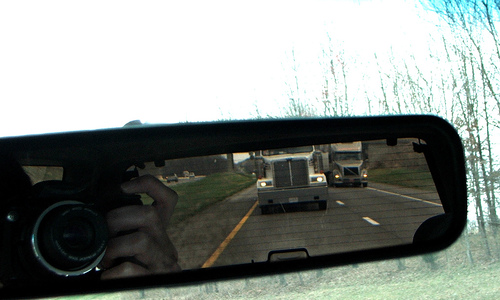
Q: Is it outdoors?
A: Yes, it is outdoors.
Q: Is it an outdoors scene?
A: Yes, it is outdoors.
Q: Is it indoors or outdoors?
A: It is outdoors.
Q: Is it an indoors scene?
A: No, it is outdoors.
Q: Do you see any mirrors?
A: Yes, there is a mirror.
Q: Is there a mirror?
A: Yes, there is a mirror.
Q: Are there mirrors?
A: Yes, there is a mirror.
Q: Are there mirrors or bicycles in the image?
A: Yes, there is a mirror.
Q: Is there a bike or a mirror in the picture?
A: Yes, there is a mirror.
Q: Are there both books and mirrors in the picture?
A: No, there is a mirror but no books.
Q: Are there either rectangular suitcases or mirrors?
A: Yes, there is a rectangular mirror.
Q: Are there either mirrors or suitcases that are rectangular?
A: Yes, the mirror is rectangular.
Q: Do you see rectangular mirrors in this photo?
A: Yes, there is a rectangular mirror.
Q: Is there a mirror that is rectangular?
A: Yes, there is a mirror that is rectangular.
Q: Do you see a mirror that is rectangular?
A: Yes, there is a mirror that is rectangular.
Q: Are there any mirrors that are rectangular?
A: Yes, there is a mirror that is rectangular.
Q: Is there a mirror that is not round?
A: Yes, there is a rectangular mirror.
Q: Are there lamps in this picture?
A: No, there are no lamps.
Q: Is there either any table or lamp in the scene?
A: No, there are no lamps or tables.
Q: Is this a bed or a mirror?
A: This is a mirror.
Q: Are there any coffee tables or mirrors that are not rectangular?
A: No, there is a mirror but it is rectangular.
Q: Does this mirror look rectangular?
A: Yes, the mirror is rectangular.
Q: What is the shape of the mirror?
A: The mirror is rectangular.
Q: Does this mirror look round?
A: No, the mirror is rectangular.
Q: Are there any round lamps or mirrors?
A: No, there is a mirror but it is rectangular.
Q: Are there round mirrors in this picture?
A: No, there is a mirror but it is rectangular.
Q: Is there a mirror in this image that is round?
A: No, there is a mirror but it is rectangular.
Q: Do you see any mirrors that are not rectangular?
A: No, there is a mirror but it is rectangular.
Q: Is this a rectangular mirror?
A: Yes, this is a rectangular mirror.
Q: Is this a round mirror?
A: No, this is a rectangular mirror.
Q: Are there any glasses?
A: No, there are no glasses.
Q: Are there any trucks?
A: Yes, there are trucks.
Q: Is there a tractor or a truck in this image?
A: Yes, there are trucks.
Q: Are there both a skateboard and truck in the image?
A: No, there are trucks but no skateboards.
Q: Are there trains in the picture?
A: No, there are no trains.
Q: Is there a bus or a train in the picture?
A: No, there are no trains or buses.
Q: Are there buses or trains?
A: No, there are no trains or buses.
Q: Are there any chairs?
A: No, there are no chairs.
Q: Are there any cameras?
A: Yes, there is a camera.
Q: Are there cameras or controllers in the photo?
A: Yes, there is a camera.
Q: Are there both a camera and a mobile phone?
A: No, there is a camera but no cell phones.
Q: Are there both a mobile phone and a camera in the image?
A: No, there is a camera but no cell phones.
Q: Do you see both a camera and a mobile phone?
A: No, there is a camera but no cell phones.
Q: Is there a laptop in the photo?
A: No, there are no laptops.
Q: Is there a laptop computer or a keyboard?
A: No, there are no laptops or keyboards.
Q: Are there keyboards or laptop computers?
A: No, there are no laptop computers or keyboards.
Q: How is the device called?
A: The device is a camera.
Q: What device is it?
A: The device is a camera.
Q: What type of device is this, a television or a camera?
A: This is a camera.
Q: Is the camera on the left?
A: Yes, the camera is on the left of the image.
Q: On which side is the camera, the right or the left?
A: The camera is on the left of the image.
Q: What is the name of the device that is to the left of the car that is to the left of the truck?
A: The device is a camera.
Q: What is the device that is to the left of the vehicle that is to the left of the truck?
A: The device is a camera.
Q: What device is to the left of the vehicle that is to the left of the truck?
A: The device is a camera.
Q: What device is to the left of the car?
A: The device is a camera.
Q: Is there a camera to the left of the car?
A: Yes, there is a camera to the left of the car.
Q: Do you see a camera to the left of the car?
A: Yes, there is a camera to the left of the car.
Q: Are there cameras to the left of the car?
A: Yes, there is a camera to the left of the car.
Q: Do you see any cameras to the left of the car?
A: Yes, there is a camera to the left of the car.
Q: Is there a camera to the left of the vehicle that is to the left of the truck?
A: Yes, there is a camera to the left of the car.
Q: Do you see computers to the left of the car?
A: No, there is a camera to the left of the car.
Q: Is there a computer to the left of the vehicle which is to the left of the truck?
A: No, there is a camera to the left of the car.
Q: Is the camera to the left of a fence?
A: No, the camera is to the left of a car.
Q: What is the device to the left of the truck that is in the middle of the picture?
A: The device is a camera.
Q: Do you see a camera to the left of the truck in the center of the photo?
A: Yes, there is a camera to the left of the truck.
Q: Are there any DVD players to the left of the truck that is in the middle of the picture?
A: No, there is a camera to the left of the truck.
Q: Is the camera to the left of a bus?
A: No, the camera is to the left of the truck.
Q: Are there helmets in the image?
A: No, there are no helmets.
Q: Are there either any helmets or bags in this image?
A: No, there are no helmets or bags.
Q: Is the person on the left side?
A: Yes, the person is on the left of the image.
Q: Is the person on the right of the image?
A: No, the person is on the left of the image.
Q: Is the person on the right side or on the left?
A: The person is on the left of the image.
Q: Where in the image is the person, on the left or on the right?
A: The person is on the left of the image.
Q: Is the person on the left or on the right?
A: The person is on the left of the image.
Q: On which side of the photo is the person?
A: The person is on the left of the image.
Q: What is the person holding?
A: The person is holding the camera.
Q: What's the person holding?
A: The person is holding the camera.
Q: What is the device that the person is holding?
A: The device is a camera.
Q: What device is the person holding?
A: The person is holding the camera.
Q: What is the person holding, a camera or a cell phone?
A: The person is holding a camera.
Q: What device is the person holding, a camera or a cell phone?
A: The person is holding a camera.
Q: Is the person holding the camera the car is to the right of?
A: Yes, the person is holding the camera.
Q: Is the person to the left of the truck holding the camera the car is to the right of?
A: Yes, the person is holding the camera.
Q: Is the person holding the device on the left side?
A: Yes, the person is holding the camera.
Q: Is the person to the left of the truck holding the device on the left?
A: Yes, the person is holding the camera.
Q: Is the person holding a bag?
A: No, the person is holding the camera.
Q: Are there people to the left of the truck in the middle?
A: Yes, there is a person to the left of the truck.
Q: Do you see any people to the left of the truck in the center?
A: Yes, there is a person to the left of the truck.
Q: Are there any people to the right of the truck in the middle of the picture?
A: No, the person is to the left of the truck.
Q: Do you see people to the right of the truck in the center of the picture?
A: No, the person is to the left of the truck.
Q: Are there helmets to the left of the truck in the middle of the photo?
A: No, there is a person to the left of the truck.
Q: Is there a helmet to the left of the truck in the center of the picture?
A: No, there is a person to the left of the truck.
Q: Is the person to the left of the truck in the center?
A: Yes, the person is to the left of the truck.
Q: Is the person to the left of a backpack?
A: No, the person is to the left of the truck.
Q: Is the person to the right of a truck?
A: No, the person is to the left of a truck.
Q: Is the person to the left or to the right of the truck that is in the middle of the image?
A: The person is to the left of the truck.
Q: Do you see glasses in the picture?
A: No, there are no glasses.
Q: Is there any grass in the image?
A: Yes, there is grass.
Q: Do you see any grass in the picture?
A: Yes, there is grass.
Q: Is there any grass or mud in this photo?
A: Yes, there is grass.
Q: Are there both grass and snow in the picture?
A: No, there is grass but no snow.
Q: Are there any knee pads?
A: No, there are no knee pads.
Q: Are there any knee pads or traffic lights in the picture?
A: No, there are no knee pads or traffic lights.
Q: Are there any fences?
A: No, there are no fences.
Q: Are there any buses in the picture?
A: No, there are no buses.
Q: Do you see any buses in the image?
A: No, there are no buses.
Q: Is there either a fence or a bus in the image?
A: No, there are no buses or fences.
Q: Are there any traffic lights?
A: No, there are no traffic lights.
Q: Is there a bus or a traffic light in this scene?
A: No, there are no traffic lights or buses.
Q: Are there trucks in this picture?
A: Yes, there is a truck.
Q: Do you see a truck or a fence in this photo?
A: Yes, there is a truck.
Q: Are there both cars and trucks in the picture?
A: Yes, there are both a truck and a car.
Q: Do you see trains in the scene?
A: No, there are no trains.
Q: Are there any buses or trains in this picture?
A: No, there are no trains or buses.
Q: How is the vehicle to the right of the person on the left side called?
A: The vehicle is a truck.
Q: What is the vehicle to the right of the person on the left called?
A: The vehicle is a truck.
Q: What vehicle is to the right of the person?
A: The vehicle is a truck.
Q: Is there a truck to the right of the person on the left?
A: Yes, there is a truck to the right of the person.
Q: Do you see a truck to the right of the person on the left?
A: Yes, there is a truck to the right of the person.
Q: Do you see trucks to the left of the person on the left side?
A: No, the truck is to the right of the person.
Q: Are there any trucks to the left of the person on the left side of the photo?
A: No, the truck is to the right of the person.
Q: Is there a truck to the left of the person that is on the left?
A: No, the truck is to the right of the person.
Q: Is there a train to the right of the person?
A: No, there is a truck to the right of the person.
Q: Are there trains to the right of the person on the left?
A: No, there is a truck to the right of the person.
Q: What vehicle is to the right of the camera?
A: The vehicle is a truck.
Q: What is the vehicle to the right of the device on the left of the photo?
A: The vehicle is a truck.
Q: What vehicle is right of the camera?
A: The vehicle is a truck.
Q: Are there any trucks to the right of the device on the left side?
A: Yes, there is a truck to the right of the camera.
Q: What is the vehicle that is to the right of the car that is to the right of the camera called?
A: The vehicle is a truck.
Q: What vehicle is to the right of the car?
A: The vehicle is a truck.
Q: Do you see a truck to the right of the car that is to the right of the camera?
A: Yes, there is a truck to the right of the car.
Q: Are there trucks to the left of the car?
A: No, the truck is to the right of the car.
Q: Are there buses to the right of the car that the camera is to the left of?
A: No, there is a truck to the right of the car.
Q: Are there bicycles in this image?
A: No, there are no bicycles.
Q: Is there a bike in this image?
A: No, there are no bikes.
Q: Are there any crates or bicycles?
A: No, there are no bicycles or crates.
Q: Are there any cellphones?
A: No, there are no cellphones.